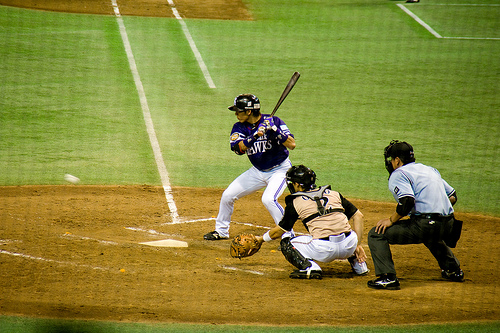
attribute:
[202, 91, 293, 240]
man — playing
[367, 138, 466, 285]
man — playing, crouching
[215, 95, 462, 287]
men — playing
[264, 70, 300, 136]
bat — black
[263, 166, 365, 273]
catcher — crouching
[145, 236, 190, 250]
plate — home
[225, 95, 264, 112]
helmet — black, protective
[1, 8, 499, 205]
grass — green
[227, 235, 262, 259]
mit — leather, brown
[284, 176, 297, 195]
mask — protective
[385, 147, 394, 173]
mask — protective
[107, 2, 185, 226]
line — white, chalk